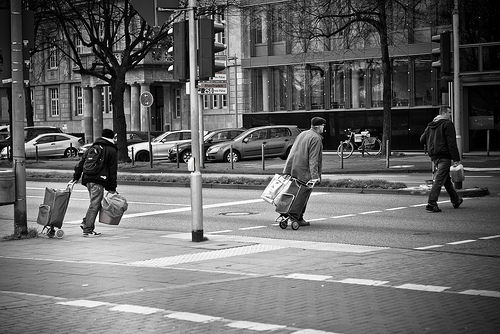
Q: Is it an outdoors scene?
A: Yes, it is outdoors.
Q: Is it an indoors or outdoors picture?
A: It is outdoors.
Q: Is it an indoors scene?
A: No, it is outdoors.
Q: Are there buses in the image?
A: No, there are no buses.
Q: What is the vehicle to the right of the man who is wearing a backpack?
A: The vehicle is a car.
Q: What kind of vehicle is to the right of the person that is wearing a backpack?
A: The vehicle is a car.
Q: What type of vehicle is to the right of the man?
A: The vehicle is a car.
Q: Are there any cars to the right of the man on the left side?
A: Yes, there is a car to the right of the man.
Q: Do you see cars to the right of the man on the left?
A: Yes, there is a car to the right of the man.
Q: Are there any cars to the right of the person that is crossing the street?
A: Yes, there is a car to the right of the man.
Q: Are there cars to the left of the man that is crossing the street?
A: No, the car is to the right of the man.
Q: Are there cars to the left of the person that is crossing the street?
A: No, the car is to the right of the man.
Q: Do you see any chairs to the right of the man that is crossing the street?
A: No, there is a car to the right of the man.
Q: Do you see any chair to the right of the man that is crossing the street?
A: No, there is a car to the right of the man.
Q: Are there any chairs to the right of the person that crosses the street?
A: No, there is a car to the right of the man.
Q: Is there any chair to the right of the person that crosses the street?
A: No, there is a car to the right of the man.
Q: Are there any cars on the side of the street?
A: Yes, there is a car on the side of the street.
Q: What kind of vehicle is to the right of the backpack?
A: The vehicle is a car.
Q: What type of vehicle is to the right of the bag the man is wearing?
A: The vehicle is a car.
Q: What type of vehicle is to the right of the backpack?
A: The vehicle is a car.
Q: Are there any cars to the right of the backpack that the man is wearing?
A: Yes, there is a car to the right of the backpack.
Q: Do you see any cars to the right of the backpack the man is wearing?
A: Yes, there is a car to the right of the backpack.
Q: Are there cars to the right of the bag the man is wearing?
A: Yes, there is a car to the right of the backpack.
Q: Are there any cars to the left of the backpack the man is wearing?
A: No, the car is to the right of the backpack.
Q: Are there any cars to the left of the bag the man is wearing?
A: No, the car is to the right of the backpack.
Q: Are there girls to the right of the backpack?
A: No, there is a car to the right of the backpack.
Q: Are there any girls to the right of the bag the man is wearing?
A: No, there is a car to the right of the backpack.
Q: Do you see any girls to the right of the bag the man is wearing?
A: No, there is a car to the right of the backpack.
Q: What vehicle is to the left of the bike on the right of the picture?
A: The vehicle is a car.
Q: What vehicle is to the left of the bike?
A: The vehicle is a car.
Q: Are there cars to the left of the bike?
A: Yes, there is a car to the left of the bike.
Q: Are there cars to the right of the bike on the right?
A: No, the car is to the left of the bike.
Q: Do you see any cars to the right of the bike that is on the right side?
A: No, the car is to the left of the bike.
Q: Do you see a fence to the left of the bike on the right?
A: No, there is a car to the left of the bike.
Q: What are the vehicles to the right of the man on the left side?
A: The vehicles are cars.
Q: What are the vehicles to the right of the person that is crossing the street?
A: The vehicles are cars.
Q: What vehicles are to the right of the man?
A: The vehicles are cars.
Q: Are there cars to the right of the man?
A: Yes, there are cars to the right of the man.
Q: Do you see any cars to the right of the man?
A: Yes, there are cars to the right of the man.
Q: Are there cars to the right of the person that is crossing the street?
A: Yes, there are cars to the right of the man.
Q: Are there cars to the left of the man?
A: No, the cars are to the right of the man.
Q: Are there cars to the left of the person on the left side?
A: No, the cars are to the right of the man.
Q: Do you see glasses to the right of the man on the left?
A: No, there are cars to the right of the man.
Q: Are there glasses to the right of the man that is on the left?
A: No, there are cars to the right of the man.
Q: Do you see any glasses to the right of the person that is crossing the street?
A: No, there are cars to the right of the man.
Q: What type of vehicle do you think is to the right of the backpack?
A: The vehicles are cars.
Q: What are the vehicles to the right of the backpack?
A: The vehicles are cars.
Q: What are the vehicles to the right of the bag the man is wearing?
A: The vehicles are cars.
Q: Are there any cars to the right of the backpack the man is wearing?
A: Yes, there are cars to the right of the backpack.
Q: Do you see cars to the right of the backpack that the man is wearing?
A: Yes, there are cars to the right of the backpack.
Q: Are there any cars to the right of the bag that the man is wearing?
A: Yes, there are cars to the right of the backpack.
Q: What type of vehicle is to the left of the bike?
A: The vehicles are cars.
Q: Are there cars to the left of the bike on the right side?
A: Yes, there are cars to the left of the bike.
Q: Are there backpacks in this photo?
A: Yes, there is a backpack.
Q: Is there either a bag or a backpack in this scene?
A: Yes, there is a backpack.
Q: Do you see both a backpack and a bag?
A: Yes, there are both a backpack and a bag.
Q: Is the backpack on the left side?
A: Yes, the backpack is on the left of the image.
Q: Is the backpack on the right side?
A: No, the backpack is on the left of the image.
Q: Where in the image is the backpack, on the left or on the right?
A: The backpack is on the left of the image.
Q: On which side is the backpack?
A: The backpack is on the left of the image.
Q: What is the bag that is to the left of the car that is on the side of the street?
A: The bag is a backpack.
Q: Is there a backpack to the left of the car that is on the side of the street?
A: Yes, there is a backpack to the left of the car.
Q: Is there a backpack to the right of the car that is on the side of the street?
A: No, the backpack is to the left of the car.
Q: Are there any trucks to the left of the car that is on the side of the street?
A: No, there is a backpack to the left of the car.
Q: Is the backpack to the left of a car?
A: Yes, the backpack is to the left of a car.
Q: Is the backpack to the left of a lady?
A: No, the backpack is to the left of a car.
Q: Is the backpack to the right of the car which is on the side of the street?
A: No, the backpack is to the left of the car.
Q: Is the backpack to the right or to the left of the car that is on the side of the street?
A: The backpack is to the left of the car.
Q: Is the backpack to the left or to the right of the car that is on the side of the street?
A: The backpack is to the left of the car.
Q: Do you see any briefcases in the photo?
A: Yes, there is a briefcase.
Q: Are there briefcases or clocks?
A: Yes, there is a briefcase.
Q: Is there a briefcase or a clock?
A: Yes, there is a briefcase.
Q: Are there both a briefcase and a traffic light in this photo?
A: Yes, there are both a briefcase and a traffic light.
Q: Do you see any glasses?
A: No, there are no glasses.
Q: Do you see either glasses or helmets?
A: No, there are no glasses or helmets.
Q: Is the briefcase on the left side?
A: Yes, the briefcase is on the left of the image.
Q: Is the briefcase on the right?
A: No, the briefcase is on the left of the image.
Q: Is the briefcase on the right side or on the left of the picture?
A: The briefcase is on the left of the image.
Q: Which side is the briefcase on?
A: The briefcase is on the left of the image.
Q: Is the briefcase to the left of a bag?
A: Yes, the briefcase is to the left of a bag.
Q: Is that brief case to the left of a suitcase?
A: No, the brief case is to the left of a bag.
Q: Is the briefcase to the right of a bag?
A: No, the briefcase is to the left of a bag.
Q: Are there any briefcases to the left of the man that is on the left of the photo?
A: Yes, there is a briefcase to the left of the man.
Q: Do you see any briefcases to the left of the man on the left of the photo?
A: Yes, there is a briefcase to the left of the man.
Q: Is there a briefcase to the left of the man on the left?
A: Yes, there is a briefcase to the left of the man.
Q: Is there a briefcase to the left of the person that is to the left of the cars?
A: Yes, there is a briefcase to the left of the man.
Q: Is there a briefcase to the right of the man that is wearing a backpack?
A: No, the briefcase is to the left of the man.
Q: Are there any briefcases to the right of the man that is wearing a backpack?
A: No, the briefcase is to the left of the man.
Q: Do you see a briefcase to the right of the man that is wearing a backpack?
A: No, the briefcase is to the left of the man.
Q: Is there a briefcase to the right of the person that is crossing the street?
A: No, the briefcase is to the left of the man.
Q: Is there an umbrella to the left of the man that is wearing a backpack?
A: No, there is a briefcase to the left of the man.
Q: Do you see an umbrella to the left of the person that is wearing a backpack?
A: No, there is a briefcase to the left of the man.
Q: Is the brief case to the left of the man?
A: Yes, the brief case is to the left of the man.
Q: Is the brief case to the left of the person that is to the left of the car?
A: Yes, the brief case is to the left of the man.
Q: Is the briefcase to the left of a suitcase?
A: No, the briefcase is to the left of the man.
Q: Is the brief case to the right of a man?
A: No, the brief case is to the left of a man.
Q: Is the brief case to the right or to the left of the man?
A: The brief case is to the left of the man.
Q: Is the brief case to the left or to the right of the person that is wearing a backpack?
A: The brief case is to the left of the man.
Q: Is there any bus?
A: No, there are no buses.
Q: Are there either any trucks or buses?
A: No, there are no buses or trucks.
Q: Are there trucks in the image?
A: No, there are no trucks.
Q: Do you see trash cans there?
A: No, there are no trash cans.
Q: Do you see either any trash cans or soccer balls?
A: No, there are no trash cans or soccer balls.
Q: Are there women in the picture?
A: No, there are no women.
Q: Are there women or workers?
A: No, there are no women or workers.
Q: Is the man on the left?
A: Yes, the man is on the left of the image.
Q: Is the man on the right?
A: No, the man is on the left of the image.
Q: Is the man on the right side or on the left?
A: The man is on the left of the image.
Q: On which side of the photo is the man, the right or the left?
A: The man is on the left of the image.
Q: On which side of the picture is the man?
A: The man is on the left of the image.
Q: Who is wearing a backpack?
A: The man is wearing a backpack.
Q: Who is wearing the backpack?
A: The man is wearing a backpack.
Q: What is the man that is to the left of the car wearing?
A: The man is wearing a backpack.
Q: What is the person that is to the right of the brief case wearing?
A: The man is wearing a backpack.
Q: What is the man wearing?
A: The man is wearing a backpack.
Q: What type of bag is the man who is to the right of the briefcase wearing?
A: The man is wearing a backpack.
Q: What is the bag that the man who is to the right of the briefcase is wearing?
A: The bag is a backpack.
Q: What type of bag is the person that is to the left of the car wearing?
A: The man is wearing a backpack.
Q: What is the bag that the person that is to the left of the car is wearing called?
A: The bag is a backpack.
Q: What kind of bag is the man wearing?
A: The man is wearing a backpack.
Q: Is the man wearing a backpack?
A: Yes, the man is wearing a backpack.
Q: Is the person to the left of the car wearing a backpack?
A: Yes, the man is wearing a backpack.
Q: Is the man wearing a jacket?
A: No, the man is wearing a backpack.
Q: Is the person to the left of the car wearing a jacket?
A: No, the man is wearing a backpack.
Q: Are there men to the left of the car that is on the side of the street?
A: Yes, there is a man to the left of the car.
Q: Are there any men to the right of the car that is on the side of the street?
A: No, the man is to the left of the car.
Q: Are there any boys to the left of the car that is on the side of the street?
A: No, there is a man to the left of the car.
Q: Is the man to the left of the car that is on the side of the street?
A: Yes, the man is to the left of the car.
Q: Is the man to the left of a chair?
A: No, the man is to the left of the car.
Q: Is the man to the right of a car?
A: No, the man is to the left of a car.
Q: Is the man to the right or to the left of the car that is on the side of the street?
A: The man is to the left of the car.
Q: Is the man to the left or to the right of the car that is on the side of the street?
A: The man is to the left of the car.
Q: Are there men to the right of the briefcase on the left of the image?
A: Yes, there is a man to the right of the briefcase.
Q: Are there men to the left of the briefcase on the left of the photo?
A: No, the man is to the right of the briefcase.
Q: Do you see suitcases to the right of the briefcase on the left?
A: No, there is a man to the right of the briefcase.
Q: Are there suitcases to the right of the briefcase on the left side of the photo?
A: No, there is a man to the right of the briefcase.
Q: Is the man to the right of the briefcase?
A: Yes, the man is to the right of the briefcase.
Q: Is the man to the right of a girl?
A: No, the man is to the right of the briefcase.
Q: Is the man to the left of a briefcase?
A: No, the man is to the right of a briefcase.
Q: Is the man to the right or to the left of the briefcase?
A: The man is to the right of the briefcase.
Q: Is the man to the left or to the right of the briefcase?
A: The man is to the right of the briefcase.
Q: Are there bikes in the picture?
A: Yes, there is a bike.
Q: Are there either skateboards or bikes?
A: Yes, there is a bike.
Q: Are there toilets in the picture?
A: No, there are no toilets.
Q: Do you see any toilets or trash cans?
A: No, there are no toilets or trash cans.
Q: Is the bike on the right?
A: Yes, the bike is on the right of the image.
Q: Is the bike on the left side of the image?
A: No, the bike is on the right of the image.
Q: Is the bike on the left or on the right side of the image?
A: The bike is on the right of the image.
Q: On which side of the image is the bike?
A: The bike is on the right of the image.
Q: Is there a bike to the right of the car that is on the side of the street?
A: Yes, there is a bike to the right of the car.